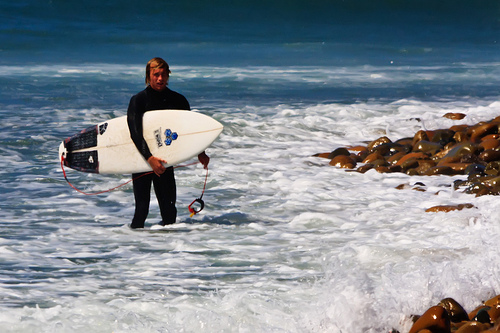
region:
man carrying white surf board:
[56, 54, 206, 233]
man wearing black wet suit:
[124, 50, 194, 231]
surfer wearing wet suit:
[129, 40, 196, 230]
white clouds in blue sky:
[16, 0, 61, 55]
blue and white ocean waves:
[248, 83, 310, 133]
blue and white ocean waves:
[278, 210, 308, 242]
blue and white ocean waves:
[8, 241, 74, 286]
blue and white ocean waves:
[96, 250, 166, 293]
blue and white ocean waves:
[30, 53, 61, 94]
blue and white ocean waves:
[285, 68, 337, 100]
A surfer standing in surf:
[43, 25, 230, 240]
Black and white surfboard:
[42, 106, 232, 179]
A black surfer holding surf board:
[126, 85, 188, 232]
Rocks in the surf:
[357, 130, 477, 173]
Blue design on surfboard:
[159, 123, 184, 151]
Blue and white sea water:
[226, 27, 443, 108]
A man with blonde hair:
[138, 54, 187, 92]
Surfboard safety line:
[181, 141, 227, 231]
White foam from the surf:
[332, 200, 447, 301]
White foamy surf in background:
[41, 58, 411, 87]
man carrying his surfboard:
[57, 57, 222, 228]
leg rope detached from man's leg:
[173, 154, 212, 213]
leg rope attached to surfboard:
[58, 150, 132, 197]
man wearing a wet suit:
[124, 57, 210, 228]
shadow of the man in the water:
[182, 209, 280, 232]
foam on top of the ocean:
[3, 97, 498, 315]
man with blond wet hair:
[124, 56, 211, 229]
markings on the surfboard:
[152, 122, 179, 149]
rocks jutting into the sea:
[313, 115, 498, 197]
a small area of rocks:
[389, 295, 498, 331]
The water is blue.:
[5, 7, 497, 66]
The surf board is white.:
[44, 105, 224, 172]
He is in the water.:
[40, 50, 220, 232]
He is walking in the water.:
[53, 55, 243, 237]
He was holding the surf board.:
[40, 48, 238, 230]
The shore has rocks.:
[335, 105, 495, 192]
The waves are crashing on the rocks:
[10, 39, 498, 311]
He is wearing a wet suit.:
[118, 88, 188, 246]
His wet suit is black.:
[118, 85, 193, 242]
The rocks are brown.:
[330, 112, 497, 192]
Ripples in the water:
[166, 276, 188, 326]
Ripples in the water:
[28, 286, 75, 328]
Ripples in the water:
[75, 274, 131, 327]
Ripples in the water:
[141, 281, 192, 327]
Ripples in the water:
[178, 255, 235, 292]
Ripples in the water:
[227, 259, 289, 304]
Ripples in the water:
[280, 211, 359, 248]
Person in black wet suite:
[88, 62, 230, 279]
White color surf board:
[40, 108, 242, 181]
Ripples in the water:
[275, 103, 342, 133]